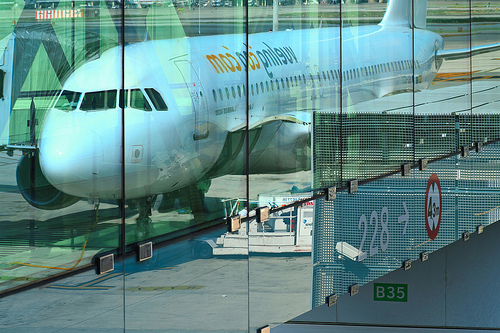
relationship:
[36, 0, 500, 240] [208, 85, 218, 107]
airplane has windows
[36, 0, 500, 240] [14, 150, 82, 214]
airplane has engine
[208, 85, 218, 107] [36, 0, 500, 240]
windows are on airplane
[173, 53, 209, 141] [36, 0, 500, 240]
door on airplane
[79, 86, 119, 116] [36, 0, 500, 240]
windshield on airplane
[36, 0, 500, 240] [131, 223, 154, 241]
airplane has wheel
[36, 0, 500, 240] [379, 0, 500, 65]
airplane has tail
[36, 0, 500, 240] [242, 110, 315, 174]
airplane has wing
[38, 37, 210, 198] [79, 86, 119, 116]
cockpit has windshield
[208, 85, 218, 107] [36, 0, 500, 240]
windows are on left side of airplane